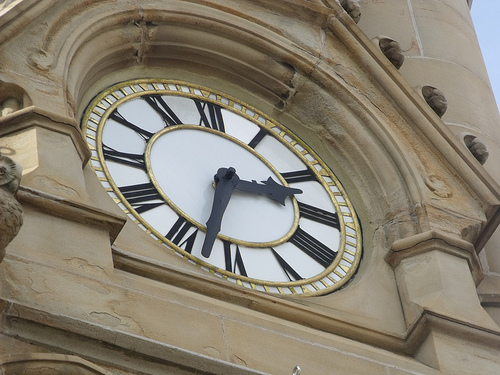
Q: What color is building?
A: Tan.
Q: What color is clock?
A: White.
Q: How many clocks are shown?
A: One.